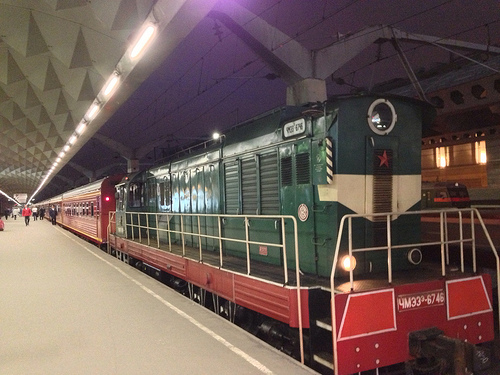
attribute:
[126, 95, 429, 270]
train car — green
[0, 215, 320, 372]
platform — long, clean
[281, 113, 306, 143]
sign — white, square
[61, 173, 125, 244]
train car — red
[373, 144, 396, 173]
star — red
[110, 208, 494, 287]
railing — silver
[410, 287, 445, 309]
numbers — white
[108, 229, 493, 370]
bottom — red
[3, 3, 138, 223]
shapes — triangle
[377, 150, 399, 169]
star — red, five pointed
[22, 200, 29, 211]
shirt — red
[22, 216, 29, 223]
pants — black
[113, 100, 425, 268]
car — green